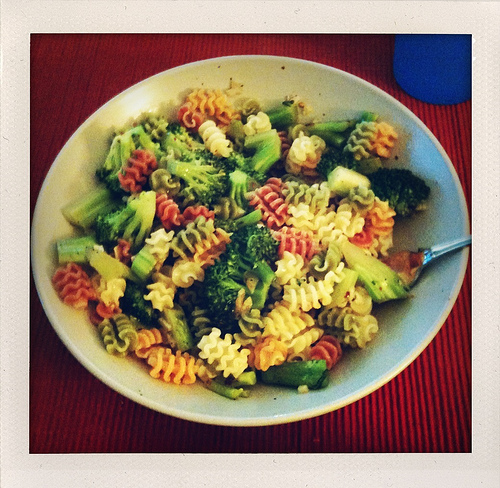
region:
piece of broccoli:
[368, 169, 425, 207]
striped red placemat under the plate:
[384, 392, 454, 448]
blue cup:
[395, 34, 465, 104]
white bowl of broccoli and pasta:
[65, 97, 425, 371]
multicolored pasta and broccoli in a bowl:
[93, 121, 377, 370]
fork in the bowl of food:
[376, 233, 468, 290]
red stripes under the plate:
[420, 365, 462, 446]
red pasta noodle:
[255, 186, 281, 225]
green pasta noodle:
[281, 178, 322, 202]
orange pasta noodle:
[150, 353, 199, 381]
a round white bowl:
[23, 45, 477, 428]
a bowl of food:
[62, 65, 436, 406]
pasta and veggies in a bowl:
[48, 75, 427, 389]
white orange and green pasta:
[243, 166, 362, 317]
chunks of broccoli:
[203, 206, 393, 346]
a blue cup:
[391, 41, 492, 146]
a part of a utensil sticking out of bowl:
[336, 180, 487, 317]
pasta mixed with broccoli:
[84, 103, 386, 344]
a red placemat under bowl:
[39, 37, 473, 459]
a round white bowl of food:
[53, 49, 471, 435]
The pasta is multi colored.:
[83, 125, 418, 378]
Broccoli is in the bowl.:
[211, 230, 278, 310]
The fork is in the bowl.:
[383, 228, 466, 288]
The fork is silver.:
[375, 198, 461, 291]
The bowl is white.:
[24, 81, 463, 418]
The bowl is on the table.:
[26, 85, 468, 443]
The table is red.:
[28, 81, 470, 444]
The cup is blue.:
[382, 40, 472, 107]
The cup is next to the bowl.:
[46, 48, 496, 458]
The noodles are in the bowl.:
[43, 84, 465, 417]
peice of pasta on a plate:
[46, 257, 94, 309]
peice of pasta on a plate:
[93, 308, 142, 361]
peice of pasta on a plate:
[137, 343, 212, 385]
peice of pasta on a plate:
[197, 326, 247, 381]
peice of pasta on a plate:
[281, 273, 341, 313]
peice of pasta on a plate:
[273, 222, 326, 254]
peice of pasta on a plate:
[246, 183, 298, 224]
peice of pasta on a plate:
[112, 143, 161, 198]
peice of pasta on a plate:
[339, 118, 381, 158]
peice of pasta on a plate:
[370, 120, 404, 161]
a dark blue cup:
[385, 30, 483, 132]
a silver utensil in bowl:
[369, 214, 493, 288]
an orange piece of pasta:
[48, 252, 116, 321]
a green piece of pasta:
[88, 308, 158, 379]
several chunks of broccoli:
[133, 91, 383, 396]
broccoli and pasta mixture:
[88, 113, 390, 385]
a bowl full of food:
[43, 55, 490, 427]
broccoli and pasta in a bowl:
[62, 96, 434, 364]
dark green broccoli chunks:
[102, 122, 288, 207]